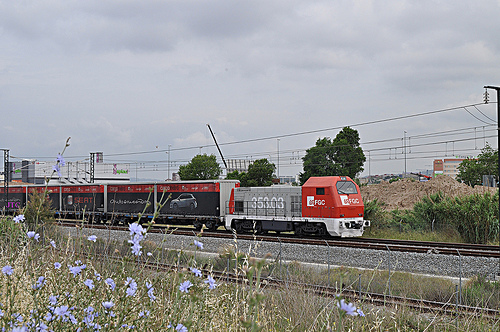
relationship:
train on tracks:
[0, 175, 372, 238] [0, 216, 499, 259]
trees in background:
[153, 121, 490, 199] [9, 92, 499, 269]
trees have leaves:
[302, 122, 365, 177] [319, 155, 344, 166]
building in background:
[427, 155, 477, 180] [0, 75, 499, 243]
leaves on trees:
[179, 123, 499, 188] [176, 125, 496, 185]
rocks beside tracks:
[43, 224, 499, 280] [0, 216, 499, 259]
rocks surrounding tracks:
[43, 224, 499, 280] [0, 216, 499, 259]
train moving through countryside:
[0, 175, 375, 237] [0, 172, 500, 326]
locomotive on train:
[227, 167, 371, 237] [0, 177, 241, 227]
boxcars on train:
[0, 177, 243, 227] [0, 175, 372, 238]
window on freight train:
[313, 182, 326, 198] [2, 171, 372, 240]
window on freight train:
[338, 174, 358, 194] [2, 171, 372, 240]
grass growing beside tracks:
[43, 230, 499, 310] [0, 216, 499, 259]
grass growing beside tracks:
[363, 221, 493, 250] [0, 216, 499, 259]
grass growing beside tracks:
[43, 230, 499, 310] [145, 260, 494, 321]